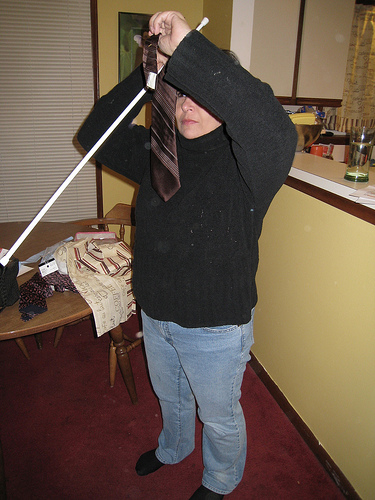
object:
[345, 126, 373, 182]
glass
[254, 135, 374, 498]
counter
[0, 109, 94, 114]
blinds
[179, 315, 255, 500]
legs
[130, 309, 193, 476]
legs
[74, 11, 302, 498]
woman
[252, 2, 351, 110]
cupboard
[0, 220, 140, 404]
table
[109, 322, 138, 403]
leg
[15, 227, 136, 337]
mess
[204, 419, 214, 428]
wrinkles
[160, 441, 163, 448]
wrinkles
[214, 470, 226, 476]
wrinkles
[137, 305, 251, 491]
jeans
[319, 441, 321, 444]
white spot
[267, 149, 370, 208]
bar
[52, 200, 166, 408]
chair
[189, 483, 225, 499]
sock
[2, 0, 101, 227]
door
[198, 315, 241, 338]
pocket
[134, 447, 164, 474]
sock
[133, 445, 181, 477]
foot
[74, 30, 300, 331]
sweater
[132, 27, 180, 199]
tie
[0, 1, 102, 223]
window